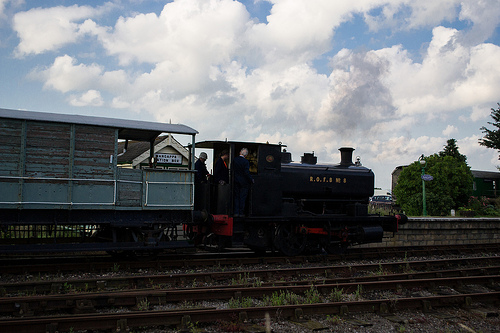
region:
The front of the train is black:
[190, 116, 442, 329]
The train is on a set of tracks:
[212, 254, 358, 329]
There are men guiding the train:
[192, 122, 339, 242]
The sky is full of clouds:
[233, 1, 480, 159]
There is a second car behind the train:
[4, 105, 200, 213]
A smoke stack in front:
[332, 139, 369, 184]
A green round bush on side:
[378, 132, 482, 219]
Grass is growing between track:
[171, 290, 384, 303]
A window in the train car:
[112, 122, 204, 174]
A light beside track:
[410, 143, 452, 235]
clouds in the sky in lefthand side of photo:
[9, 3, 242, 92]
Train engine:
[202, 131, 391, 250]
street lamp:
[409, 155, 435, 215]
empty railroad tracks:
[11, 264, 498, 319]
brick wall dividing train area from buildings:
[401, 216, 498, 250]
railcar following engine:
[0, 100, 199, 244]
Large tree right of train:
[392, 144, 480, 216]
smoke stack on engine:
[326, 141, 368, 175]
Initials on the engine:
[300, 169, 364, 192]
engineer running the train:
[182, 144, 219, 204]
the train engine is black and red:
[201, 134, 413, 254]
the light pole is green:
[407, 151, 436, 215]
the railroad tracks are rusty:
[64, 268, 404, 325]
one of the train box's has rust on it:
[6, 101, 199, 247]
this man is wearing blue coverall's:
[231, 145, 261, 220]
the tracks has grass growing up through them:
[208, 270, 468, 324]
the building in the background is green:
[466, 157, 496, 203]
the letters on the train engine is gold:
[281, 147, 387, 211]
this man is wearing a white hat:
[189, 146, 219, 204]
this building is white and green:
[120, 128, 195, 174]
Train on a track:
[1, 100, 395, 247]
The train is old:
[191, 126, 423, 280]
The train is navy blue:
[194, 127, 401, 257]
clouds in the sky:
[127, 2, 469, 113]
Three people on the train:
[191, 148, 280, 225]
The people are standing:
[186, 145, 268, 224]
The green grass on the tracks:
[219, 282, 380, 309]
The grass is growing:
[233, 290, 383, 307]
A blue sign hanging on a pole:
[407, 147, 442, 232]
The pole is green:
[417, 146, 436, 221]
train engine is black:
[197, 126, 382, 241]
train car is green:
[3, 124, 210, 237]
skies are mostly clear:
[66, 1, 495, 140]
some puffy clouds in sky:
[131, 1, 488, 138]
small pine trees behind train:
[405, 93, 498, 152]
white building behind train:
[115, 116, 204, 178]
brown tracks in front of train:
[18, 245, 498, 317]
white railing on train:
[14, 151, 192, 211]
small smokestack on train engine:
[334, 143, 359, 178]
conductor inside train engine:
[187, 141, 230, 213]